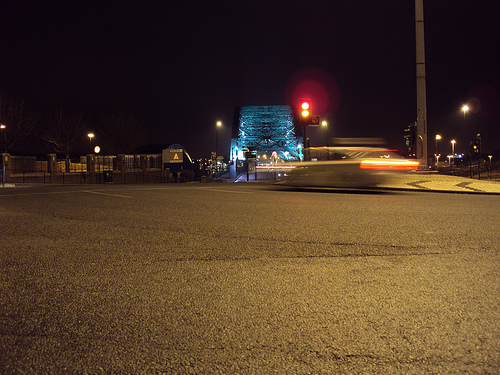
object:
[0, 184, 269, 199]
lines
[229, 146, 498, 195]
car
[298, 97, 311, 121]
signal light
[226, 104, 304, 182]
trusses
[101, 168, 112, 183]
receptacle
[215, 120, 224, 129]
bright light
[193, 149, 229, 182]
buildings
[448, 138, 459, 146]
light outside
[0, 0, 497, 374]
scene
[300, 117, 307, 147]
oile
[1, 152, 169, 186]
fence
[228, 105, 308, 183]
stone wall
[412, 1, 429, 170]
pole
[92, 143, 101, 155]
lamps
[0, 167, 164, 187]
wall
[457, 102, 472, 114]
lamps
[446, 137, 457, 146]
lamps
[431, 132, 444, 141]
lamps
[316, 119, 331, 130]
lamps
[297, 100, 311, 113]
light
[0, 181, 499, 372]
ground